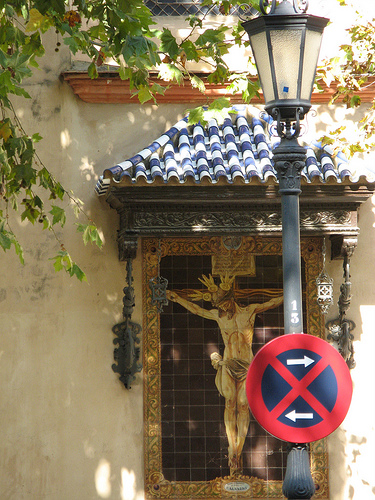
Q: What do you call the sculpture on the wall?
A: A crucifix.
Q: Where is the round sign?
A: On the lamppost.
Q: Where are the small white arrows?
A: On the sign.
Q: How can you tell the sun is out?
A: It is casting shadows.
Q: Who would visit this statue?
A: Religious people.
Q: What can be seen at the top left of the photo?
A: Leafs on a branch.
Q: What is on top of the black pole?
A: A lamp.